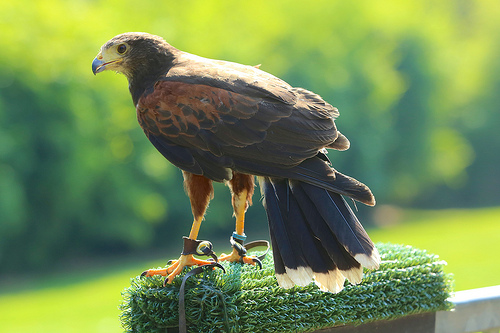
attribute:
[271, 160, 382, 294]
tail feathers — dark brown, white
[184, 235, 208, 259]
strap — leather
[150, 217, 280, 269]
feet — bright yellow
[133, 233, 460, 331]
astro turf — green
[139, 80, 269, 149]
wing feathers — light brown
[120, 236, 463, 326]
perch — green covered 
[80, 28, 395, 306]
bird — tail feathers, Black, white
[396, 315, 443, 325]
railing — green covering.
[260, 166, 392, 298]
feathers — bird, Brown, tan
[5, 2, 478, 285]
trees — row, distance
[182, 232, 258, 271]
cord — bird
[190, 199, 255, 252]
leg — skinny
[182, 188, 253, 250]
leg — skinny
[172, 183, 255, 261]
legs — bird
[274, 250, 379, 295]
tip — black, white 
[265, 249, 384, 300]
tip — white , black 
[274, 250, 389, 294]
tip — black , white  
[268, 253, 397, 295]
tip — white  , black  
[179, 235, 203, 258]
strap — small round leather brown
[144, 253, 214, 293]
claws — large pointy sharp curved 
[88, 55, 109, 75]
beak — small curved pointy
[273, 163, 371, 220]
feather — long black thin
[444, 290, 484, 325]
fence — long wooden brown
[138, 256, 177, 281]
talon — sharp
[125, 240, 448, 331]
mat — green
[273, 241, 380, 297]
tips — white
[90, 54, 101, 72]
beak — curved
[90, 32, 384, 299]
bird — green rail., stands, standing up, short beak, large brown feathered, large, pradatory, domesticated, big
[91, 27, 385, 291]
predator — dangerous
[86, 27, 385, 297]
hawk — domesticated, brown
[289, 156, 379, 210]
feather — black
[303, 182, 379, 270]
feather — black, large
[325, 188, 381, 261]
feather — black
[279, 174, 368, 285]
feather — black, large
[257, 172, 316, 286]
feather — black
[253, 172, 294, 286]
feather — large, black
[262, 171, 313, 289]
feather — large, black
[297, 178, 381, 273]
feather — large, black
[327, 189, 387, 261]
feather — large, black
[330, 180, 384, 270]
feather — large, black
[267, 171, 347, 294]
feather — large, black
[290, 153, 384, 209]
feather — black, large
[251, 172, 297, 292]
feather — black, large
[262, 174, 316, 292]
feather — black, large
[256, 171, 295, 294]
feather — large, black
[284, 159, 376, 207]
feather — large, black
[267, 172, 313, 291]
feather — black, large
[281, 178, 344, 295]
feather — black, large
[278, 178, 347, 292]
feather — large, black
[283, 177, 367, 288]
feather — large, black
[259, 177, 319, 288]
feather — black, large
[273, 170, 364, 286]
feather — large, black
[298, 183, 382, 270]
feather — large, black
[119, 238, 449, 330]
perch — green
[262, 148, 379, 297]
tail — brown and white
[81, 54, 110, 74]
beak — yellow, black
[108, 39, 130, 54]
eye — brown, colored, of a bird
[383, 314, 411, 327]
wood — brown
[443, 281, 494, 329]
wall — white, colored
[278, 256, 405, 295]
tips — white